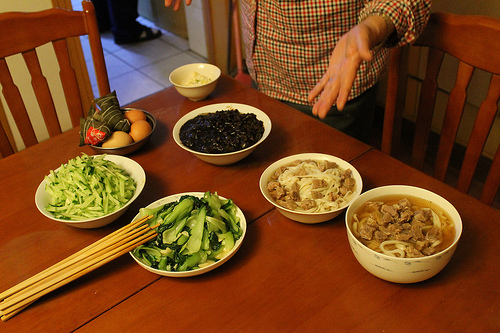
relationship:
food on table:
[28, 89, 475, 309] [271, 256, 351, 323]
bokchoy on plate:
[129, 206, 244, 291] [160, 182, 249, 218]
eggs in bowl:
[28, 89, 475, 309] [142, 111, 379, 201]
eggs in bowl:
[100, 122, 152, 143] [142, 111, 379, 201]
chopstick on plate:
[30, 238, 188, 285] [160, 182, 249, 218]